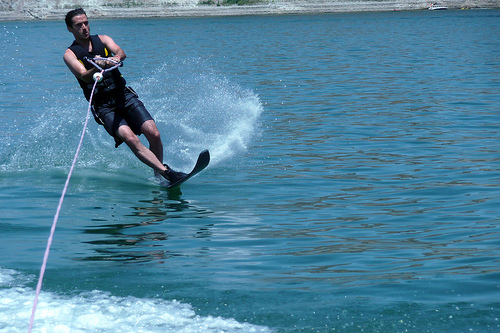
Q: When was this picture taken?
A: During the day.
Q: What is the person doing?
A: Water skiing.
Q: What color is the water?
A: Blue.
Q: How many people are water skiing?
A: One.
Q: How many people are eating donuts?
A: Zero.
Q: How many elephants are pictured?
A: Zero.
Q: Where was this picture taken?
A: In the water.